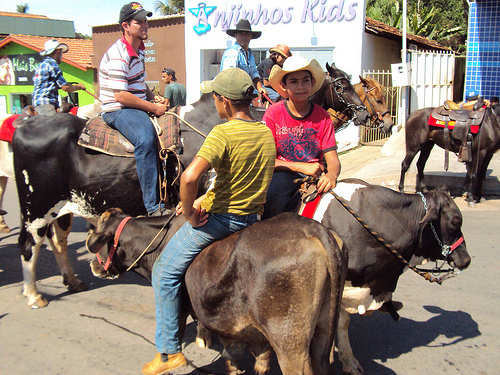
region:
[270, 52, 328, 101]
cowboy hat on boy's head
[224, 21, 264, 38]
black cowboy hat on man's head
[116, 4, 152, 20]
black baseball cap on mans head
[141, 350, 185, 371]
brown boot on boys left foot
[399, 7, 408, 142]
white pole standing outside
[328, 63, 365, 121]
dark brown horse's head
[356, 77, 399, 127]
light brown horse's head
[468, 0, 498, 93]
blue checkered wall outside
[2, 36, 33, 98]
a small green building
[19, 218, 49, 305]
black and white cow's rear right leg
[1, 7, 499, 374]
people are riding cows and horses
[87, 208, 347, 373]
closest cow is brown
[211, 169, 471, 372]
child is riding black and white cow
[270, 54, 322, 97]
kid is wearing cowboy hat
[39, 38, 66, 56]
man on horse wearing white cowboy hat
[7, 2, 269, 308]
man is riding black and white cow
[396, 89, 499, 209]
brown horse standing with no rider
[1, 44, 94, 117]
building is painted green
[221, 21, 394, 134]
two horses and riders behind cows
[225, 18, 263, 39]
cowboy hat is black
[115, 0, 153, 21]
a black baseball cap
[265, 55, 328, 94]
a boy's beige hat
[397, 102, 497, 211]
part of a brown horse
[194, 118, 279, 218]
a boy's short sleeve shirt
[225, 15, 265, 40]
a man's black hat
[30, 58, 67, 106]
a man's blue and white shirt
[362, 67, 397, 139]
a white fence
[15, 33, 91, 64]
the roof of a building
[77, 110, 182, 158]
part of a horse saddle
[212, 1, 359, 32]
the name of a business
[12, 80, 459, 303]
people sitting on cows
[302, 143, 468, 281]
harness on cows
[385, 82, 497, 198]
horse next to the building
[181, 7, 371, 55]
sign on the front of store front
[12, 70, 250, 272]
man on left riding black and white cow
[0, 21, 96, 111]
lime green building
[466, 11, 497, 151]
building on right has a blue ceramic tile face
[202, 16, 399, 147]
two men riding horses behind the men on cows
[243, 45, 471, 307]
boy with red shirt riding on cow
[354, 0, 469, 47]
trees behind the building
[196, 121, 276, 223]
yellow shirt on a boy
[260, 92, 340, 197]
red shirt on a boy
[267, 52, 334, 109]
cowboy hat on a boy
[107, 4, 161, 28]
black baseball cap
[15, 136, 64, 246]
black and white spots on a cow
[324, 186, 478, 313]
black and white cow with a bridle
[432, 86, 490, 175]
saddle on a brown horse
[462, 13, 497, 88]
two different blues on a tile wall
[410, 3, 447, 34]
tree tops behind a house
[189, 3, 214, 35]
the letter A made up to look like an angel